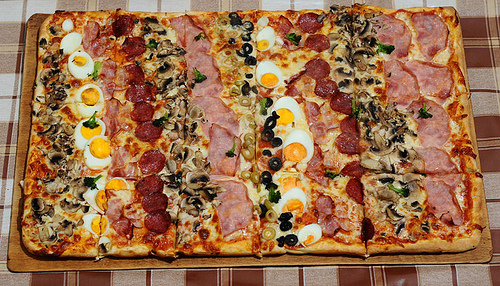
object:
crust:
[363, 172, 480, 254]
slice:
[361, 170, 483, 253]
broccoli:
[388, 179, 402, 194]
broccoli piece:
[81, 108, 101, 130]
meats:
[108, 20, 173, 229]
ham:
[209, 179, 251, 237]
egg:
[270, 97, 303, 132]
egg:
[282, 129, 312, 169]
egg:
[280, 191, 306, 220]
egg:
[290, 227, 320, 241]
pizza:
[21, 8, 484, 260]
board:
[6, 4, 493, 271]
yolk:
[90, 138, 111, 159]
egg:
[69, 84, 106, 117]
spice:
[271, 120, 346, 174]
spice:
[395, 19, 475, 64]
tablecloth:
[9, 0, 500, 285]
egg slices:
[248, 11, 329, 243]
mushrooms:
[32, 168, 74, 194]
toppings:
[30, 7, 460, 245]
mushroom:
[46, 65, 67, 82]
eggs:
[297, 224, 322, 245]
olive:
[261, 227, 275, 239]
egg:
[75, 131, 113, 171]